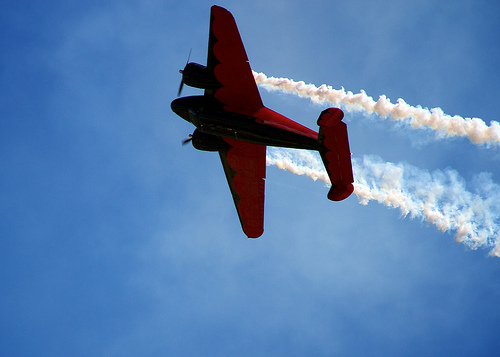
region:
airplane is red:
[159, 28, 363, 204]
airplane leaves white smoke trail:
[208, 58, 496, 238]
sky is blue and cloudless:
[37, 0, 197, 287]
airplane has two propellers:
[152, 40, 214, 149]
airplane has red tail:
[296, 96, 363, 211]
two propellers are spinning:
[159, 54, 214, 164]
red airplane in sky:
[140, 25, 355, 237]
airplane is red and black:
[189, 13, 360, 229]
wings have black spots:
[179, 10, 313, 270]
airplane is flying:
[167, 13, 363, 245]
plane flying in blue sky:
[121, 6, 358, 264]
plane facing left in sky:
[161, 0, 360, 242]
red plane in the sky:
[145, 0, 355, 261]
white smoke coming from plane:
[230, 43, 499, 243]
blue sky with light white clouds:
[12, 25, 165, 352]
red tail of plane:
[311, 95, 361, 215]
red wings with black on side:
[205, 6, 280, 278]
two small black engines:
[170, 57, 225, 158]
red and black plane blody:
[157, 76, 332, 157]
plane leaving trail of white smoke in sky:
[168, 12, 497, 317]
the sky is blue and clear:
[73, 102, 200, 345]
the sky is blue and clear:
[11, 85, 242, 332]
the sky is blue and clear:
[36, 177, 184, 351]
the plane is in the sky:
[170, 0, 351, 236]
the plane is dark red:
[155, 0, 350, 235]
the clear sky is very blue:
[0, 0, 495, 350]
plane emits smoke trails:
[250, 65, 495, 275]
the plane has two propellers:
[160, 50, 220, 155]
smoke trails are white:
[245, 60, 495, 255]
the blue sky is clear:
[0, 0, 495, 355]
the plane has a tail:
[315, 100, 350, 195]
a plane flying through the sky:
[165, 1, 495, 267]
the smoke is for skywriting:
[248, 65, 498, 250]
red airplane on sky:
[131, 8, 396, 325]